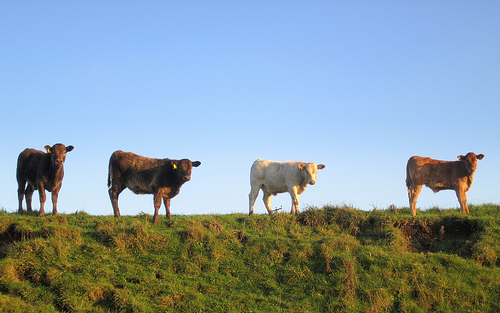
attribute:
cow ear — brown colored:
[41, 140, 56, 155]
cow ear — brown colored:
[62, 141, 75, 155]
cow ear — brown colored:
[163, 156, 180, 172]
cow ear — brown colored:
[188, 155, 203, 170]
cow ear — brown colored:
[453, 149, 466, 162]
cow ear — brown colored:
[473, 150, 485, 164]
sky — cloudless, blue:
[0, 0, 499, 216]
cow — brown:
[400, 148, 486, 222]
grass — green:
[2, 205, 497, 309]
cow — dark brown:
[107, 149, 198, 224]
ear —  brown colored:
[455, 152, 466, 160]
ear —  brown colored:
[475, 152, 483, 162]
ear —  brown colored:
[190, 156, 201, 168]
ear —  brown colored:
[65, 143, 75, 155]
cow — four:
[406, 147, 488, 212]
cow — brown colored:
[12, 140, 77, 216]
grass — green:
[157, 221, 402, 307]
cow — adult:
[15, 143, 75, 215]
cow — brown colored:
[11, 142, 84, 211]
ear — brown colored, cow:
[190, 156, 202, 171]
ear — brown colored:
[477, 152, 485, 159]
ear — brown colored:
[316, 162, 326, 169]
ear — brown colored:
[298, 161, 306, 170]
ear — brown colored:
[66, 145, 74, 151]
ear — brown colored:
[43, 145, 52, 152]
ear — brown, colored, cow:
[315, 160, 330, 171]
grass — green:
[58, 228, 355, 298]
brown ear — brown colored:
[43, 143, 53, 153]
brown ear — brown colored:
[64, 145, 76, 153]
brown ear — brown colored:
[190, 159, 201, 171]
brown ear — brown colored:
[453, 152, 466, 161]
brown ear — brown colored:
[476, 150, 483, 158]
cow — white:
[223, 150, 328, 210]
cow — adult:
[7, 138, 77, 213]